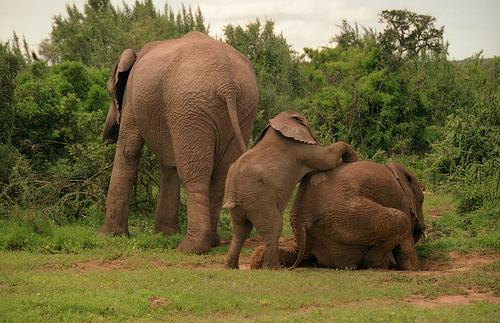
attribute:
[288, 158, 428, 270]
elephant — kneeling, mother, playing, baby, digging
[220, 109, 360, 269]
elephant — baby, climbing, playing, little, standing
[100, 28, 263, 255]
elephant — searching, matriarch, large, mother, walking, mama, standing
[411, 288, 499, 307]
patch — dirt, clay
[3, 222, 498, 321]
grass — growing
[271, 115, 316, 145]
ear — flappy, gray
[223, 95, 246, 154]
tail — brown, long, gray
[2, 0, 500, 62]
sky — overcast, gray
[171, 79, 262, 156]
hindquarters — wrinkled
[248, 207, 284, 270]
leg — hind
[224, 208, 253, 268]
leg — hind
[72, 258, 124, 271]
patch — dirt